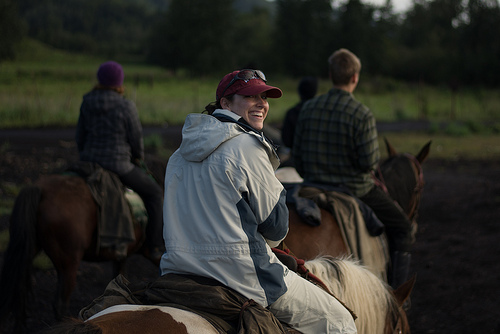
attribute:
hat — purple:
[95, 59, 124, 83]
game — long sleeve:
[7, 45, 489, 327]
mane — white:
[307, 258, 392, 332]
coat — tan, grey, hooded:
[113, 94, 380, 298]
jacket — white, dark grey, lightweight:
[158, 109, 291, 309]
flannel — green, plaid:
[274, 90, 376, 195]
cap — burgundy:
[218, 68, 284, 108]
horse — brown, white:
[80, 257, 412, 332]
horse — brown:
[3, 146, 178, 332]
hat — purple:
[95, 63, 125, 91]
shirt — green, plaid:
[290, 87, 379, 196]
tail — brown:
[5, 184, 44, 322]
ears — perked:
[382, 136, 432, 163]